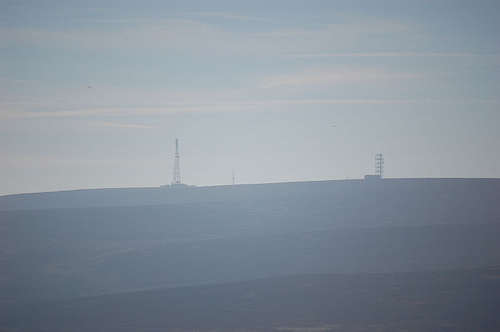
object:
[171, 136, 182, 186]
tower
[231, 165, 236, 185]
structure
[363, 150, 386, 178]
structure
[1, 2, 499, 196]
sky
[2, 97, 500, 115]
cloud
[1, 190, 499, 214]
ripple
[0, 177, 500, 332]
ground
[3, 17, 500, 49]
cloud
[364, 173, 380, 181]
building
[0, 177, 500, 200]
horizon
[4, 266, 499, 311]
ridge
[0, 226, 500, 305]
hill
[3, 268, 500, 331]
hill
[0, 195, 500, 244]
hill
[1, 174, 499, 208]
hill